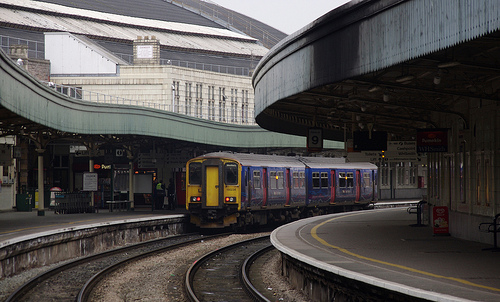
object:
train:
[181, 149, 381, 231]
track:
[6, 233, 231, 301]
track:
[185, 235, 275, 302]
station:
[3, 1, 499, 301]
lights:
[222, 196, 230, 204]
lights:
[194, 196, 203, 200]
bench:
[405, 197, 425, 227]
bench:
[53, 190, 97, 215]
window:
[185, 160, 204, 186]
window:
[222, 162, 237, 185]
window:
[310, 177, 322, 188]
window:
[338, 178, 348, 189]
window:
[275, 178, 282, 189]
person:
[164, 178, 175, 211]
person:
[155, 177, 166, 211]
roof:
[0, 0, 231, 30]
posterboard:
[432, 206, 450, 236]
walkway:
[268, 204, 500, 302]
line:
[308, 206, 500, 291]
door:
[330, 167, 338, 201]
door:
[353, 166, 361, 198]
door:
[283, 167, 293, 207]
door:
[259, 168, 270, 206]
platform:
[0, 205, 189, 282]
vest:
[154, 181, 163, 192]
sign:
[92, 156, 115, 176]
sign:
[83, 172, 97, 192]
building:
[0, 0, 427, 215]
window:
[176, 80, 181, 94]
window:
[187, 98, 190, 116]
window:
[194, 85, 199, 100]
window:
[209, 101, 213, 119]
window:
[223, 96, 228, 102]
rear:
[302, 154, 381, 210]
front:
[185, 151, 308, 226]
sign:
[305, 133, 321, 152]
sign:
[353, 129, 390, 151]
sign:
[413, 130, 450, 154]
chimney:
[130, 34, 162, 64]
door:
[203, 165, 222, 207]